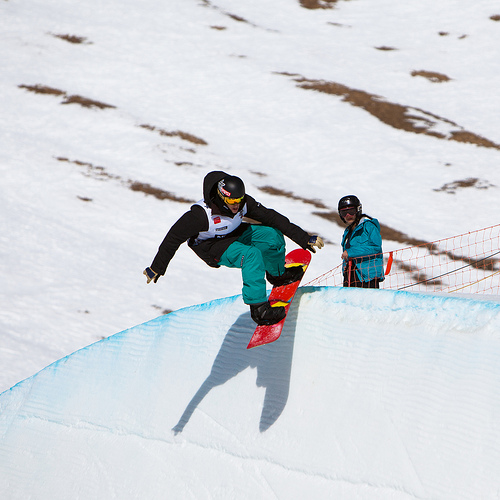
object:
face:
[222, 191, 246, 216]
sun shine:
[312, 322, 500, 500]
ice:
[0, 285, 500, 499]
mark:
[75, 191, 97, 205]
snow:
[0, 0, 500, 393]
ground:
[0, 0, 500, 390]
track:
[1, 201, 95, 247]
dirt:
[60, 92, 118, 112]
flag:
[384, 252, 396, 274]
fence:
[302, 221, 500, 304]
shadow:
[170, 284, 323, 437]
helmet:
[216, 175, 251, 204]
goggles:
[228, 196, 246, 208]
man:
[142, 170, 328, 327]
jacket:
[148, 170, 313, 275]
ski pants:
[215, 226, 288, 309]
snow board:
[246, 245, 314, 349]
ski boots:
[247, 297, 288, 326]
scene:
[0, 0, 500, 498]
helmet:
[336, 192, 365, 223]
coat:
[338, 214, 386, 285]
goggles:
[337, 207, 358, 217]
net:
[302, 222, 500, 300]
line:
[0, 285, 500, 398]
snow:
[4, 284, 500, 498]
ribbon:
[377, 249, 396, 277]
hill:
[3, 283, 500, 499]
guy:
[336, 193, 386, 291]